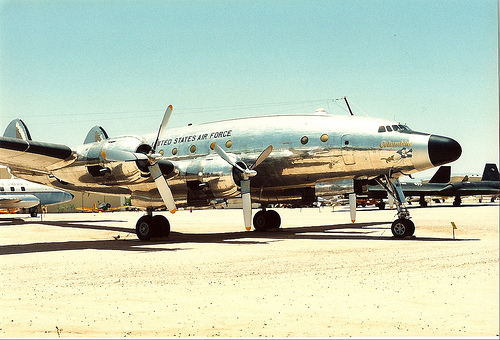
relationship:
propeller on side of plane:
[208, 140, 276, 236] [0, 103, 462, 240]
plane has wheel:
[0, 103, 462, 240] [388, 215, 415, 239]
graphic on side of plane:
[378, 146, 417, 166] [0, 103, 462, 240]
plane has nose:
[0, 103, 462, 240] [398, 128, 462, 173]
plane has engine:
[0, 103, 462, 240] [128, 141, 251, 203]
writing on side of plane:
[152, 128, 236, 149] [0, 103, 462, 240]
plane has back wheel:
[0, 103, 462, 240] [134, 216, 161, 244]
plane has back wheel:
[0, 103, 462, 240] [252, 208, 276, 235]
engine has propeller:
[128, 141, 251, 203] [208, 140, 276, 236]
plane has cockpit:
[0, 103, 462, 240] [361, 117, 413, 151]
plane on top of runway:
[0, 103, 462, 240] [1, 199, 499, 338]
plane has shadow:
[0, 103, 462, 240] [1, 214, 482, 258]